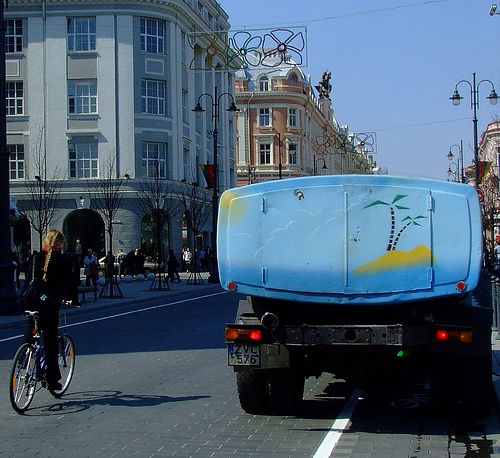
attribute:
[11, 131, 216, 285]
trees — young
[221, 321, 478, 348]
rear lights — glowing, red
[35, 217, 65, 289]
hair — blonde, braided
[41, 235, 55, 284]
braid — long, blond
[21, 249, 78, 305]
coat — black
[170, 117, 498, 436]
truck — blue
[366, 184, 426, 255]
flower — red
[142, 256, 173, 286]
cage — protective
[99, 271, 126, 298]
cage — protective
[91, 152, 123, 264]
tree — bare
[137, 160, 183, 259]
tree — bare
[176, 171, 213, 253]
tree — bare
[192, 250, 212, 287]
cage — protective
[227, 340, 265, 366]
tag — black, white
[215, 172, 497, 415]
truck — blue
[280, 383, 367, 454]
line — white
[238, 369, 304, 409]
tires — dual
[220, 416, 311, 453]
pavers — gray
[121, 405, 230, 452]
pavers — gray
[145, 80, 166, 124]
window — white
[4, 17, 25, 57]
window — white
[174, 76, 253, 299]
post — light